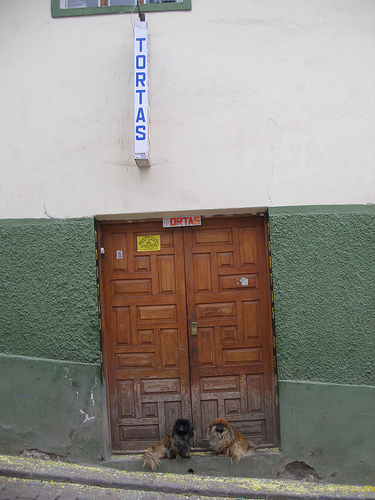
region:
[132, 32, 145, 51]
a letter written in blue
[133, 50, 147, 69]
a letter written in blue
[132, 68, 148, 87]
a letter written in blue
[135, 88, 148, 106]
a letter written in blue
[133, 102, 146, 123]
a letter written in blue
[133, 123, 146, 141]
a letter written in blue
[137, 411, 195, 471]
a dog lying down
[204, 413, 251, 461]
a dog lying down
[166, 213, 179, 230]
a letter written in red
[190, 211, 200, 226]
a letter written in red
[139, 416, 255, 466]
a pair of small dogs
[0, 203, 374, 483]
green paint on the wall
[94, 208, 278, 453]
a pair of wooden doors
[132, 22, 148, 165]
a sign with blue letters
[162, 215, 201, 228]
a sign with red letters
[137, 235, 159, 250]
a yellow sign on the door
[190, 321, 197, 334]
the handle on the door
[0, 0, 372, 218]
white paint on the building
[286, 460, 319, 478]
a hole in the wall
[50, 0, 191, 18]
a window in the wall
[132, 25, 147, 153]
the sign says TORTAS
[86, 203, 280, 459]
the door is brown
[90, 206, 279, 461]
the door is wood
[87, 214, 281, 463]
the door is carved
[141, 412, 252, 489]
the dogs are outside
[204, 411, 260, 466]
the dog is brown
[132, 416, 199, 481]
the dog is black and brown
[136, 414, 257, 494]
the dogs look dirty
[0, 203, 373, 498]
the building is green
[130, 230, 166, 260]
a yellow sticker is on the door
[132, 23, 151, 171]
a sign hanging in front of the building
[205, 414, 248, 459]
a brown dog sitting in front of the doors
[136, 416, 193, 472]
a dark brown dog sitting next the other dog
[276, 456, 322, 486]
a cat laying down on the ground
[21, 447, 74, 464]
another cat laying down on the ground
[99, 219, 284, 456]
the tall brown doors behind the two dogs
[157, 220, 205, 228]
a small sign above the dogs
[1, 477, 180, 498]
the street in front of the store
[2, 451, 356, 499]
the sidewalk for people to walk on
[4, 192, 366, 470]
the wall of the building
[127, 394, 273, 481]
Three dogs sitting in front of a door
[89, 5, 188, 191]
Tortas sign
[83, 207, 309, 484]
Three dogs sitting in front of a brown door.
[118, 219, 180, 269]
Yellow sign on the brown door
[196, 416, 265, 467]
Brown dog sitting in front of a brown door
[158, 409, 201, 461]
Black dog sitting in front of a brown door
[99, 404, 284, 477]
Three dogs in front of a brown door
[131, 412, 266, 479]
One dog laying down in front of a door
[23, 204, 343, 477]
Brown door within a green wall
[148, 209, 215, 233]
Tortas sign with red letters